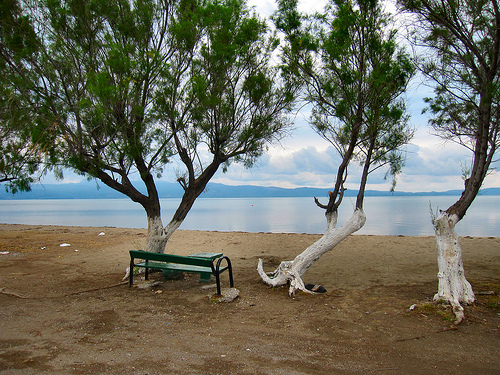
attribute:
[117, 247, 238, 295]
park bench — empty, green, metal, small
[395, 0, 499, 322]
tree — slanted, curvy, painted, green, swooping, crooked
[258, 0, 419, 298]
tree — slanted, green, swooping, painted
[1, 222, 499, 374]
beach — dirt, gravel, sandy, light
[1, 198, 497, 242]
water — smooth, calm, empty, river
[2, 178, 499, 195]
mountains — distant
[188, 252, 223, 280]
table — green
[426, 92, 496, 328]
trunk — white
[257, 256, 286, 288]
root — protruding